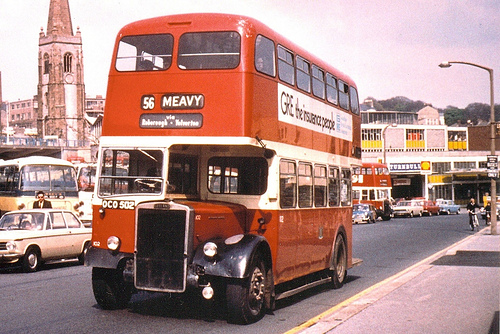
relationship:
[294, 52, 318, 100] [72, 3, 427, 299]
glass window on bus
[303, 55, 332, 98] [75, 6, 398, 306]
glass window on bus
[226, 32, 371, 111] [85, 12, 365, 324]
windows are attached to bus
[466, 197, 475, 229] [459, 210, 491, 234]
man on bicycle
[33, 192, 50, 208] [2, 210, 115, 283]
man by car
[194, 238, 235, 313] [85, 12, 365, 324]
lights on bus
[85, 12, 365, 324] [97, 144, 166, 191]
bus has window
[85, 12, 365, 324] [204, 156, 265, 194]
bus has window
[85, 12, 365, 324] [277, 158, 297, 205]
bus has window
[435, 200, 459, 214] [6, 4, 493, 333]
car in city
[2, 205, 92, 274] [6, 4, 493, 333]
car in city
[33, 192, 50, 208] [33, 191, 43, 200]
man wears sunglasses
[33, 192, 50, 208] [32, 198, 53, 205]
man wears suit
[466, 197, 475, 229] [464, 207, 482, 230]
man rides bicycle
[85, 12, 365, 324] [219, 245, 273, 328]
bus has wheel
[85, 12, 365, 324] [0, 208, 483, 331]
bus are on road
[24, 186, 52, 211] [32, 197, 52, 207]
man wearing suit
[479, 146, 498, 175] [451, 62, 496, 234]
sign posted on a lamp post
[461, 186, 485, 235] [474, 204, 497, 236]
man in bicycle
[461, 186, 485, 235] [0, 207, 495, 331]
man in street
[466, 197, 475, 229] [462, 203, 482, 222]
man wearing sweater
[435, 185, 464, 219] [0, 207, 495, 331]
car parked in street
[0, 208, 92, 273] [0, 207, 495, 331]
car parked in street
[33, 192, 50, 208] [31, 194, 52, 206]
man wearing suit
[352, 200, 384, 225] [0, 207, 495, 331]
car in street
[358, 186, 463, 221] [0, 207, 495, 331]
cars parked in street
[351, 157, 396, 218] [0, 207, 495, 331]
truck in street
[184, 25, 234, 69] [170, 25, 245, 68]
woman looking though window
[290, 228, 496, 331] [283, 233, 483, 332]
sidewalk with a curb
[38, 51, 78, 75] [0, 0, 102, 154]
belfry of a church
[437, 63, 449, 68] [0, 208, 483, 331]
light by road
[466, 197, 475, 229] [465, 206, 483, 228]
man walking their bicycle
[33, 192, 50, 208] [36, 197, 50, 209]
man wearing suit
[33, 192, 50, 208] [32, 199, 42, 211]
man wearing tie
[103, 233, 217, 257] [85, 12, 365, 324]
headlight on bus